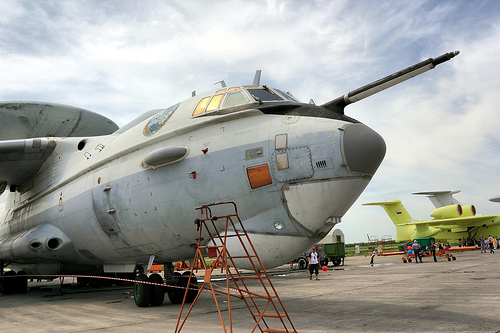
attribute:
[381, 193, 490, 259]
airplane — yellow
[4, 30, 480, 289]
aircraft — large, grey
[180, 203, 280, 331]
stepladder — small, orange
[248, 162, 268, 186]
hatch — orange, small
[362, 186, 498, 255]
plane — enormous, green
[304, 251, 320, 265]
shirt — white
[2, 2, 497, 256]
sky — white, blue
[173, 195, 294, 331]
utility ladder — orange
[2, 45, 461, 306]
airplane — large, displayed